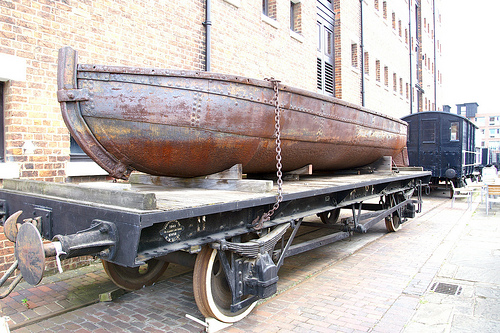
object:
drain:
[430, 282, 462, 296]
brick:
[7, 307, 200, 333]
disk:
[13, 223, 45, 287]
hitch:
[14, 219, 121, 286]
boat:
[56, 46, 409, 183]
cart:
[0, 156, 432, 324]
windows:
[424, 122, 434, 140]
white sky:
[436, 0, 500, 116]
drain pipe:
[360, 0, 364, 107]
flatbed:
[0, 171, 432, 226]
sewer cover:
[430, 282, 462, 296]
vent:
[430, 282, 463, 296]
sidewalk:
[0, 165, 500, 333]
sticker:
[159, 220, 185, 243]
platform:
[0, 156, 432, 333]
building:
[442, 101, 500, 153]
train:
[0, 110, 499, 323]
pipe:
[201, 0, 212, 72]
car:
[400, 111, 500, 199]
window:
[290, 0, 301, 35]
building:
[0, 0, 447, 288]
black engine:
[400, 110, 500, 199]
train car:
[398, 111, 479, 178]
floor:
[0, 165, 500, 333]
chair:
[450, 180, 473, 208]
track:
[0, 181, 475, 333]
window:
[317, 58, 334, 95]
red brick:
[0, 167, 500, 333]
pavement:
[1, 167, 500, 333]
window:
[351, 43, 357, 67]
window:
[364, 51, 369, 75]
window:
[376, 60, 380, 82]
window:
[384, 66, 389, 87]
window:
[400, 78, 403, 95]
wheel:
[192, 244, 250, 323]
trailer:
[0, 156, 432, 323]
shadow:
[0, 219, 387, 333]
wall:
[95, 10, 167, 50]